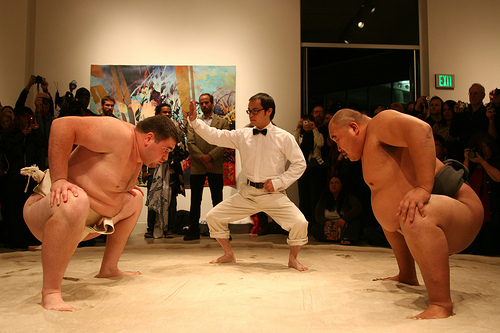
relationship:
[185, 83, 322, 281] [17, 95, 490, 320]
referee behind wrestlers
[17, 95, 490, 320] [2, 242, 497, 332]
wrestlers in ring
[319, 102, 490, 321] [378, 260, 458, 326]
sumo wrestler has feet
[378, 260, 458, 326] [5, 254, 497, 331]
feet in sand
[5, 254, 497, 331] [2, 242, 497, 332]
sand in ring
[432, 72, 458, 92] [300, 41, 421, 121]
exit sign near doorway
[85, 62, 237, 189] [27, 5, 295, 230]
picture on wall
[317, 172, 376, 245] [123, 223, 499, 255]
person sitting on floor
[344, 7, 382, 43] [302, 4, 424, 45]
lights reflected in window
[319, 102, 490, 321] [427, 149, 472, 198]
sumo wrestler wearing loincloth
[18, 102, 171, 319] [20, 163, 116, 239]
sumo wrestler wearing loincloth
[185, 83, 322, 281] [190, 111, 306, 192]
referee wearing shirt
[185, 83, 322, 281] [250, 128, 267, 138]
referee wearing bowtie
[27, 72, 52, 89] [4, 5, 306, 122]
camera in air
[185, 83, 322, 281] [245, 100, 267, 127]
referee has face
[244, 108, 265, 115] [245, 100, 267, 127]
glasses on face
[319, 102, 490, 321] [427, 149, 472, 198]
sumo wrestler in loincloth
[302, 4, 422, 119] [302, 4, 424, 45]
nighttime outside window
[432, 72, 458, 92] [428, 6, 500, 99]
exit sign on wall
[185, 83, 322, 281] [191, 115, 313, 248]
referee wearing white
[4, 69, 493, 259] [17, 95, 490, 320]
spectators behind wrestlers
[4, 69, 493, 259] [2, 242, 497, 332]
spectators behind ring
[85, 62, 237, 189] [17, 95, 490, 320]
picture behind wrestlers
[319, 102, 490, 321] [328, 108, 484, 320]
sumo wrestler on sumo wrestler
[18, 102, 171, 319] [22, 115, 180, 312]
sumo wrestler on sumo wrestler